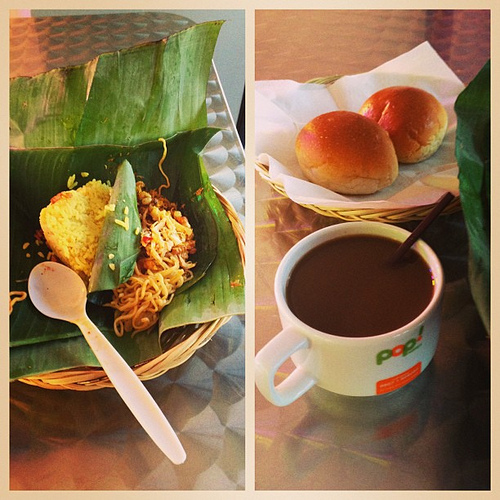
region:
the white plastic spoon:
[28, 257, 187, 462]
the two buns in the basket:
[296, 93, 442, 175]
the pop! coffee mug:
[263, 222, 442, 396]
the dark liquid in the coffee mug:
[301, 243, 418, 313]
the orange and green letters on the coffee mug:
[372, 329, 431, 365]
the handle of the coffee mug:
[256, 326, 323, 402]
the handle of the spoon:
[80, 322, 187, 464]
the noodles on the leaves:
[126, 214, 165, 334]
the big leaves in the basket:
[23, 68, 205, 165]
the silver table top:
[23, 15, 168, 47]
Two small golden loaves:
[291, 87, 453, 187]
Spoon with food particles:
[23, 256, 213, 463]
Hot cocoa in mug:
[303, 228, 428, 330]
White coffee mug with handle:
[273, 232, 455, 414]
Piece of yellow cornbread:
[46, 177, 112, 257]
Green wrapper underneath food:
[17, 73, 244, 313]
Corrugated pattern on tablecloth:
[216, 140, 241, 197]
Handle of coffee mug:
[259, 326, 311, 410]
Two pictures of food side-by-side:
[8, 44, 488, 490]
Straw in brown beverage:
[392, 185, 458, 260]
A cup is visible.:
[249, 225, 404, 448]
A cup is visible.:
[296, 166, 411, 377]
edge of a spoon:
[172, 452, 178, 462]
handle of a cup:
[283, 400, 288, 402]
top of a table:
[363, 417, 376, 441]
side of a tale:
[221, 98, 228, 118]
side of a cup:
[372, 347, 389, 373]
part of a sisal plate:
[186, 334, 196, 360]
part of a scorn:
[343, 121, 366, 164]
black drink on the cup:
[359, 302, 377, 327]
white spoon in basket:
[27, 258, 153, 408]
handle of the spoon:
[94, 347, 175, 436]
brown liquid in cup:
[310, 234, 402, 334]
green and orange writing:
[365, 332, 420, 378]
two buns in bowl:
[285, 70, 440, 210]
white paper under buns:
[265, 75, 325, 121]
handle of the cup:
[256, 325, 311, 395]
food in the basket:
[47, 165, 182, 335]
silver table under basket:
[65, 13, 117, 45]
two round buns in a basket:
[313, 71, 447, 195]